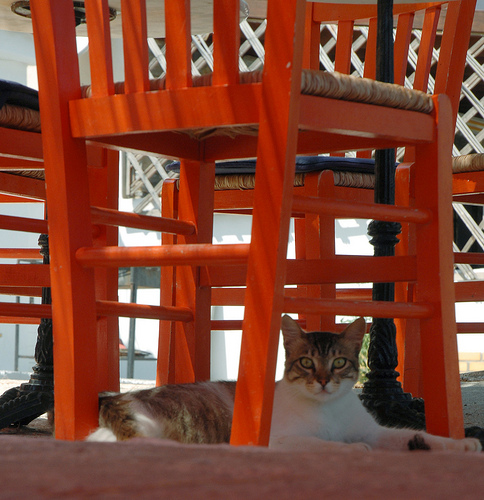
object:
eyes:
[333, 357, 347, 369]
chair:
[27, 2, 477, 447]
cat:
[95, 313, 481, 454]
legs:
[42, 124, 97, 447]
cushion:
[77, 66, 438, 111]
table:
[0, 0, 481, 447]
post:
[128, 239, 143, 386]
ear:
[340, 316, 366, 355]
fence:
[69, 4, 484, 161]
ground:
[458, 371, 484, 427]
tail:
[97, 395, 142, 442]